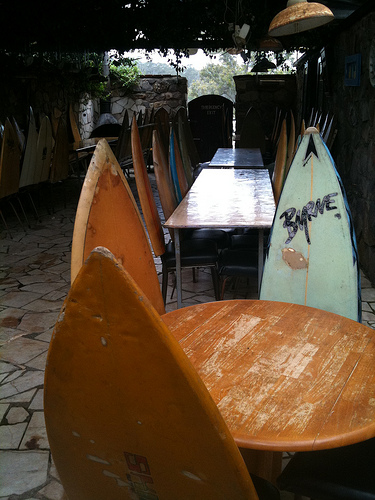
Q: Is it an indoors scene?
A: Yes, it is indoors.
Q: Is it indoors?
A: Yes, it is indoors.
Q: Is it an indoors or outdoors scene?
A: It is indoors.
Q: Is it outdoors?
A: No, it is indoors.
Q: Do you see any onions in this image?
A: Yes, there are onions.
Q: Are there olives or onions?
A: Yes, there are onions.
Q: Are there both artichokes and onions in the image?
A: No, there are onions but no artichokes.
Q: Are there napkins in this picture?
A: No, there are no napkins.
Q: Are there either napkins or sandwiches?
A: No, there are no napkins or sandwiches.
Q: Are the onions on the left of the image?
A: Yes, the onions are on the left of the image.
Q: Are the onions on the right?
A: No, the onions are on the left of the image.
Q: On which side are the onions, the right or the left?
A: The onions are on the left of the image.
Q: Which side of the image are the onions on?
A: The onions are on the left of the image.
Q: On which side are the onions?
A: The onions are on the left of the image.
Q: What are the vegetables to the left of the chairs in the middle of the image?
A: The vegetables are onions.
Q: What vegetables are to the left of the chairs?
A: The vegetables are onions.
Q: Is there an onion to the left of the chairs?
A: Yes, there are onions to the left of the chairs.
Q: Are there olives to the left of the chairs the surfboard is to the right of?
A: No, there are onions to the left of the chairs.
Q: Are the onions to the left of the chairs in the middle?
A: Yes, the onions are to the left of the chairs.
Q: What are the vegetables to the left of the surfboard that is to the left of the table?
A: The vegetables are onions.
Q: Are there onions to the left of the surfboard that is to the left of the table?
A: Yes, there are onions to the left of the surfboard.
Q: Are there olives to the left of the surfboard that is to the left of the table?
A: No, there are onions to the left of the surfboard.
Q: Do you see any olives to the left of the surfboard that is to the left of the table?
A: No, there are onions to the left of the surfboard.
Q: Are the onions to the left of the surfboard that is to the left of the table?
A: Yes, the onions are to the left of the surfboard.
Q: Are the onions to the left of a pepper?
A: No, the onions are to the left of the surfboard.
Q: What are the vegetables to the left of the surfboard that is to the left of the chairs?
A: The vegetables are onions.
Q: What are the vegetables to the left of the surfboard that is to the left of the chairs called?
A: The vegetables are onions.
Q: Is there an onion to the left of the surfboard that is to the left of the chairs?
A: Yes, there are onions to the left of the surfboard.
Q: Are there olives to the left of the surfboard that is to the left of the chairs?
A: No, there are onions to the left of the surfboard.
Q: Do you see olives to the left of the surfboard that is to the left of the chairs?
A: No, there are onions to the left of the surfboard.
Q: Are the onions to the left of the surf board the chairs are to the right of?
A: Yes, the onions are to the left of the surfboard.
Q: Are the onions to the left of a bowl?
A: No, the onions are to the left of the surfboard.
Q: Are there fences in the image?
A: No, there are no fences.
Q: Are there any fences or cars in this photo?
A: No, there are no fences or cars.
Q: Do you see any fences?
A: No, there are no fences.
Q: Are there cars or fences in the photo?
A: No, there are no fences or cars.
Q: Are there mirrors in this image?
A: No, there are no mirrors.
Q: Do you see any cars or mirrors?
A: No, there are no mirrors or cars.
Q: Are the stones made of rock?
A: Yes, the stones are made of rock.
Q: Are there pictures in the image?
A: No, there are no pictures.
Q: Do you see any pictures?
A: No, there are no pictures.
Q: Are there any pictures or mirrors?
A: No, there are no pictures or mirrors.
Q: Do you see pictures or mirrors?
A: No, there are no pictures or mirrors.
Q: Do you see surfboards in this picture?
A: Yes, there is a surfboard.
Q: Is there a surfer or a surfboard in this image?
A: Yes, there is a surfboard.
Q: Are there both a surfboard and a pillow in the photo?
A: No, there is a surfboard but no pillows.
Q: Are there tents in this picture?
A: No, there are no tents.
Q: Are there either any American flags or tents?
A: No, there are no tents or American flags.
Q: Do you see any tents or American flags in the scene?
A: No, there are no tents or American flags.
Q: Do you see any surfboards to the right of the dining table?
A: Yes, there is a surfboard to the right of the dining table.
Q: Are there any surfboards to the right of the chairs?
A: Yes, there is a surfboard to the right of the chairs.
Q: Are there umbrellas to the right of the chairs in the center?
A: No, there is a surfboard to the right of the chairs.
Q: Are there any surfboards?
A: Yes, there is a surfboard.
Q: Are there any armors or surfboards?
A: Yes, there is a surfboard.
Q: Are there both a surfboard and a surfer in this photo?
A: No, there is a surfboard but no surfers.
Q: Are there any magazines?
A: No, there are no magazines.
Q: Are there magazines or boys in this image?
A: No, there are no magazines or boys.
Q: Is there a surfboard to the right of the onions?
A: Yes, there is a surfboard to the right of the onions.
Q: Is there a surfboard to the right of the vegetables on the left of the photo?
A: Yes, there is a surfboard to the right of the onions.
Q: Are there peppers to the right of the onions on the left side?
A: No, there is a surfboard to the right of the onions.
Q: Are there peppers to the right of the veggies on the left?
A: No, there is a surfboard to the right of the onions.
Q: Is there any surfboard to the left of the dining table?
A: Yes, there is a surfboard to the left of the dining table.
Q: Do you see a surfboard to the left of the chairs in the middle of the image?
A: Yes, there is a surfboard to the left of the chairs.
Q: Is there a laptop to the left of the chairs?
A: No, there is a surfboard to the left of the chairs.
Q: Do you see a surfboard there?
A: Yes, there is a surfboard.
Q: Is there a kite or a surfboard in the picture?
A: Yes, there is a surfboard.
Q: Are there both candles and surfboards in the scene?
A: No, there is a surfboard but no candles.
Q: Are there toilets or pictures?
A: No, there are no pictures or toilets.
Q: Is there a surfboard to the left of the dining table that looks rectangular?
A: Yes, there is a surfboard to the left of the dining table.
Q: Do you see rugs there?
A: No, there are no rugs.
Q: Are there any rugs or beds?
A: No, there are no rugs or beds.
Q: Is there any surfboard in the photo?
A: Yes, there is a surfboard.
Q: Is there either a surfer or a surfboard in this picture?
A: Yes, there is a surfboard.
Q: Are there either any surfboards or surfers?
A: Yes, there is a surfboard.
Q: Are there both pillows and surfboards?
A: No, there is a surfboard but no pillows.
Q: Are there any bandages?
A: No, there are no bandages.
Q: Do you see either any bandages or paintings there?
A: No, there are no bandages or paintings.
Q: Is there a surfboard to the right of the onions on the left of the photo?
A: Yes, there is a surfboard to the right of the onions.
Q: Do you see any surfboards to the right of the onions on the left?
A: Yes, there is a surfboard to the right of the onions.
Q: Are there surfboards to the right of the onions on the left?
A: Yes, there is a surfboard to the right of the onions.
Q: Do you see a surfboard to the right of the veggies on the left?
A: Yes, there is a surfboard to the right of the onions.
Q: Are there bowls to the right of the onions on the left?
A: No, there is a surfboard to the right of the onions.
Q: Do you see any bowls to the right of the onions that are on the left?
A: No, there is a surfboard to the right of the onions.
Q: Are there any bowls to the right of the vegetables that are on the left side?
A: No, there is a surfboard to the right of the onions.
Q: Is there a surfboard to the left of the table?
A: Yes, there is a surfboard to the left of the table.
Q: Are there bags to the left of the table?
A: No, there is a surfboard to the left of the table.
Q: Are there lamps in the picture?
A: Yes, there is a lamp.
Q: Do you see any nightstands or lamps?
A: Yes, there is a lamp.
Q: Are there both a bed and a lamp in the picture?
A: No, there is a lamp but no beds.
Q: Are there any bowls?
A: No, there are no bowls.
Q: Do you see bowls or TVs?
A: No, there are no bowls or tvs.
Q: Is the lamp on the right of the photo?
A: Yes, the lamp is on the right of the image.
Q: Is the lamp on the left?
A: No, the lamp is on the right of the image.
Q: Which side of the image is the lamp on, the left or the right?
A: The lamp is on the right of the image.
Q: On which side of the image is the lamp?
A: The lamp is on the right of the image.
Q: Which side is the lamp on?
A: The lamp is on the right of the image.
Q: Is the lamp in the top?
A: Yes, the lamp is in the top of the image.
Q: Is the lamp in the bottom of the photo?
A: No, the lamp is in the top of the image.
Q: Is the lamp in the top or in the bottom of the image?
A: The lamp is in the top of the image.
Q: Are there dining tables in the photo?
A: Yes, there is a dining table.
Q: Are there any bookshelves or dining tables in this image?
A: Yes, there is a dining table.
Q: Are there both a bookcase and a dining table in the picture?
A: No, there is a dining table but no bookcases.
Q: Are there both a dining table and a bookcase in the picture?
A: No, there is a dining table but no bookcases.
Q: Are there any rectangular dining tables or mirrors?
A: Yes, there is a rectangular dining table.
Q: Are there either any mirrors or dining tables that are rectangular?
A: Yes, the dining table is rectangular.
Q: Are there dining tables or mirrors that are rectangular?
A: Yes, the dining table is rectangular.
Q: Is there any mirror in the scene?
A: No, there are no mirrors.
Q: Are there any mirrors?
A: No, there are no mirrors.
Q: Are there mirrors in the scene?
A: No, there are no mirrors.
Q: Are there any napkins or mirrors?
A: No, there are no mirrors or napkins.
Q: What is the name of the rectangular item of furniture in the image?
A: The piece of furniture is a dining table.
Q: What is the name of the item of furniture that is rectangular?
A: The piece of furniture is a dining table.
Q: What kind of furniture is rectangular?
A: The furniture is a dining table.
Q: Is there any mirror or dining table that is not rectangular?
A: No, there is a dining table but it is rectangular.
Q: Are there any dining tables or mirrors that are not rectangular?
A: No, there is a dining table but it is rectangular.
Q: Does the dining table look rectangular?
A: Yes, the dining table is rectangular.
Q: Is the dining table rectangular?
A: Yes, the dining table is rectangular.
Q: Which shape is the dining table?
A: The dining table is rectangular.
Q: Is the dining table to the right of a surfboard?
A: Yes, the dining table is to the right of a surfboard.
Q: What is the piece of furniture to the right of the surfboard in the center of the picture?
A: The piece of furniture is a dining table.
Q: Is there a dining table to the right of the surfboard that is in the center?
A: Yes, there is a dining table to the right of the surfboard.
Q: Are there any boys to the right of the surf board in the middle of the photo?
A: No, there is a dining table to the right of the surfboard.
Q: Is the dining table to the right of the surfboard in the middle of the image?
A: Yes, the dining table is to the right of the surfboard.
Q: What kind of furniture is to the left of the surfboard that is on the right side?
A: The piece of furniture is a dining table.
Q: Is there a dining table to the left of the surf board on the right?
A: Yes, there is a dining table to the left of the surfboard.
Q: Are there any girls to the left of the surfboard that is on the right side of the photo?
A: No, there is a dining table to the left of the surfboard.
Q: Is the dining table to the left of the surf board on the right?
A: Yes, the dining table is to the left of the surf board.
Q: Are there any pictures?
A: No, there are no pictures.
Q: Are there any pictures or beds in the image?
A: No, there are no pictures or beds.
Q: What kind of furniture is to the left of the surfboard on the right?
A: The pieces of furniture are chairs.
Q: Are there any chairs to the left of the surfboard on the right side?
A: Yes, there are chairs to the left of the surfboard.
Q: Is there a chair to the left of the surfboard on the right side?
A: Yes, there are chairs to the left of the surfboard.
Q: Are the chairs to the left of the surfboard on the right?
A: Yes, the chairs are to the left of the surf board.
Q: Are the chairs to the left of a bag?
A: No, the chairs are to the left of the surf board.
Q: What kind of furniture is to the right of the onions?
A: The pieces of furniture are chairs.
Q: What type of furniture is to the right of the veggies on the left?
A: The pieces of furniture are chairs.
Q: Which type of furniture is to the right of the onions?
A: The pieces of furniture are chairs.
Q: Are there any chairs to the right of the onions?
A: Yes, there are chairs to the right of the onions.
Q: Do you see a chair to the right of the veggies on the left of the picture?
A: Yes, there are chairs to the right of the onions.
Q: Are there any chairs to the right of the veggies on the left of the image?
A: Yes, there are chairs to the right of the onions.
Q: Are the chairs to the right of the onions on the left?
A: Yes, the chairs are to the right of the onions.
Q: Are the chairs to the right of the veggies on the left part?
A: Yes, the chairs are to the right of the onions.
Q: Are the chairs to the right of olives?
A: No, the chairs are to the right of the onions.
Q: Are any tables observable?
A: Yes, there is a table.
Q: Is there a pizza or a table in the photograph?
A: Yes, there is a table.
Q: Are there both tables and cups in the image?
A: No, there is a table but no cups.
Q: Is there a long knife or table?
A: Yes, there is a long table.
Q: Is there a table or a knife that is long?
A: Yes, the table is long.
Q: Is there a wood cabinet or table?
A: Yes, there is a wood table.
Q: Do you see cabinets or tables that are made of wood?
A: Yes, the table is made of wood.